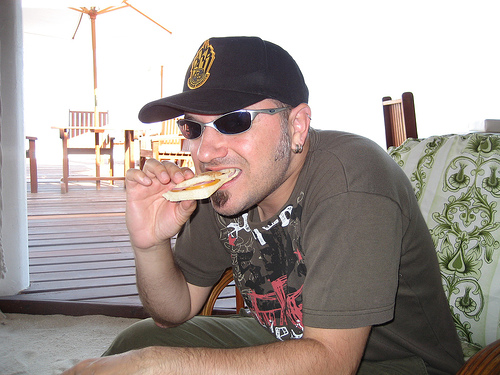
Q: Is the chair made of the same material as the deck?
A: Yes, both the chair and the deck are made of wood.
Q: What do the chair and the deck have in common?
A: The material, both the chair and the deck are wooden.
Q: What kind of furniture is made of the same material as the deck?
A: The chair is made of the same material as the deck.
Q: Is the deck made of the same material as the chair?
A: Yes, both the deck and the chair are made of wood.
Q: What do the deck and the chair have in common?
A: The material, both the deck and the chair are wooden.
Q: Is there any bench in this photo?
A: Yes, there is a bench.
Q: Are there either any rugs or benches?
A: Yes, there is a bench.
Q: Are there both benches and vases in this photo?
A: No, there is a bench but no vases.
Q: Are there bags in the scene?
A: No, there are no bags.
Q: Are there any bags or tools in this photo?
A: No, there are no bags or tools.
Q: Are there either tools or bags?
A: No, there are no bags or tools.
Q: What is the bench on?
A: The bench is on the deck.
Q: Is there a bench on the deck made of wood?
A: Yes, there is a bench on the deck.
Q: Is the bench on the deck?
A: Yes, the bench is on the deck.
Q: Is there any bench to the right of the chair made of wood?
A: Yes, there is a bench to the right of the chair.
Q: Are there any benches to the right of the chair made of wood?
A: Yes, there is a bench to the right of the chair.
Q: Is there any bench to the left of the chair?
A: No, the bench is to the right of the chair.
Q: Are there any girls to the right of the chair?
A: No, there is a bench to the right of the chair.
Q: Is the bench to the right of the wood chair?
A: Yes, the bench is to the right of the chair.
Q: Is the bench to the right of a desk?
A: No, the bench is to the right of the chair.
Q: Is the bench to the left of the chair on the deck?
A: No, the bench is to the right of the chair.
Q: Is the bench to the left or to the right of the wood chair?
A: The bench is to the right of the chair.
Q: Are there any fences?
A: No, there are no fences.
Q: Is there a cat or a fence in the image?
A: No, there are no fences or cats.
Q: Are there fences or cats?
A: No, there are no fences or cats.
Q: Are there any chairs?
A: Yes, there is a chair.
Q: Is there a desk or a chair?
A: Yes, there is a chair.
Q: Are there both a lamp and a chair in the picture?
A: No, there is a chair but no lamps.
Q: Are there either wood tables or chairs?
A: Yes, there is a wood chair.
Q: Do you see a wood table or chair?
A: Yes, there is a wood chair.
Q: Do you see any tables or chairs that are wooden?
A: Yes, the chair is wooden.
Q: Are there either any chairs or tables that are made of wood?
A: Yes, the chair is made of wood.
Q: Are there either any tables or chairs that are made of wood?
A: Yes, the chair is made of wood.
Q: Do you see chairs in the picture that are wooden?
A: Yes, there is a wood chair.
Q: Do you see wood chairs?
A: Yes, there is a wood chair.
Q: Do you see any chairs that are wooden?
A: Yes, there is a wood chair.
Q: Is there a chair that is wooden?
A: Yes, there is a chair that is wooden.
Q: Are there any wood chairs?
A: Yes, there is a chair that is made of wood.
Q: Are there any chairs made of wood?
A: Yes, there is a chair that is made of wood.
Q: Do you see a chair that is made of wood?
A: Yes, there is a chair that is made of wood.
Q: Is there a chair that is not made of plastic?
A: Yes, there is a chair that is made of wood.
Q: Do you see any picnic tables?
A: No, there are no picnic tables.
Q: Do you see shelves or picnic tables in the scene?
A: No, there are no picnic tables or shelves.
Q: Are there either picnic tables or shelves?
A: No, there are no picnic tables or shelves.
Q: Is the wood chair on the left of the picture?
A: Yes, the chair is on the left of the image.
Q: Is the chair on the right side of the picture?
A: No, the chair is on the left of the image.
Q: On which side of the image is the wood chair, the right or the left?
A: The chair is on the left of the image.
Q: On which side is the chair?
A: The chair is on the left of the image.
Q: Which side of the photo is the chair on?
A: The chair is on the left of the image.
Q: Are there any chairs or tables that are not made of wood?
A: No, there is a chair but it is made of wood.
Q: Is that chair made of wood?
A: Yes, the chair is made of wood.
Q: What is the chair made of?
A: The chair is made of wood.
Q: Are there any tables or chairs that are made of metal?
A: No, there is a chair but it is made of wood.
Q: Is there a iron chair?
A: No, there is a chair but it is made of wood.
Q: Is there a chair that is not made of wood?
A: No, there is a chair but it is made of wood.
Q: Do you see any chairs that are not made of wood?
A: No, there is a chair but it is made of wood.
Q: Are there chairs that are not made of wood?
A: No, there is a chair but it is made of wood.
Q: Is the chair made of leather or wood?
A: The chair is made of wood.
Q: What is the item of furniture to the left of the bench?
A: The piece of furniture is a chair.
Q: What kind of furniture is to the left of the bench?
A: The piece of furniture is a chair.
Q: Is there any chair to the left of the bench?
A: Yes, there is a chair to the left of the bench.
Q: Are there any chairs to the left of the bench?
A: Yes, there is a chair to the left of the bench.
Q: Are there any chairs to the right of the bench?
A: No, the chair is to the left of the bench.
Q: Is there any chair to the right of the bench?
A: No, the chair is to the left of the bench.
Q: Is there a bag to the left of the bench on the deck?
A: No, there is a chair to the left of the bench.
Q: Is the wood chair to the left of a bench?
A: Yes, the chair is to the left of a bench.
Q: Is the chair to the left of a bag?
A: No, the chair is to the left of a bench.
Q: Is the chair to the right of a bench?
A: No, the chair is to the left of a bench.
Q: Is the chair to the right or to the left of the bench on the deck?
A: The chair is to the left of the bench.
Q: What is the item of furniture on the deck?
A: The piece of furniture is a chair.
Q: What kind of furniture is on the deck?
A: The piece of furniture is a chair.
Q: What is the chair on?
A: The chair is on the deck.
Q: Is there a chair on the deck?
A: Yes, there is a chair on the deck.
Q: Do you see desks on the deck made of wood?
A: No, there is a chair on the deck.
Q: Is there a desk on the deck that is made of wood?
A: No, there is a chair on the deck.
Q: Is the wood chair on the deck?
A: Yes, the chair is on the deck.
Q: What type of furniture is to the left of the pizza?
A: The piece of furniture is a chair.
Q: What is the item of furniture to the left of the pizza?
A: The piece of furniture is a chair.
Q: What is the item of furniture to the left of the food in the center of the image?
A: The piece of furniture is a chair.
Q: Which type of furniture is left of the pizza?
A: The piece of furniture is a chair.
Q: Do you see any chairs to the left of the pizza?
A: Yes, there is a chair to the left of the pizza.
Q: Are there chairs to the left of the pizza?
A: Yes, there is a chair to the left of the pizza.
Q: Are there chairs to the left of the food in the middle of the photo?
A: Yes, there is a chair to the left of the pizza.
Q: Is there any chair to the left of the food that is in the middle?
A: Yes, there is a chair to the left of the pizza.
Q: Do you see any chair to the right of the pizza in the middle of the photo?
A: No, the chair is to the left of the pizza.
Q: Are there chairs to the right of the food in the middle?
A: No, the chair is to the left of the pizza.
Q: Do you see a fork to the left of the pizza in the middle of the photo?
A: No, there is a chair to the left of the pizza.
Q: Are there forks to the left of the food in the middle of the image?
A: No, there is a chair to the left of the pizza.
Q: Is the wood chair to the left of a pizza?
A: Yes, the chair is to the left of a pizza.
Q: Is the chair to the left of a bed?
A: No, the chair is to the left of a pizza.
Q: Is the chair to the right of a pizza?
A: No, the chair is to the left of a pizza.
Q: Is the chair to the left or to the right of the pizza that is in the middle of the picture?
A: The chair is to the left of the pizza.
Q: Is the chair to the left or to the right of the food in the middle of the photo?
A: The chair is to the left of the pizza.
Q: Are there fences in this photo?
A: No, there are no fences.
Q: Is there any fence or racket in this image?
A: No, there are no fences or rackets.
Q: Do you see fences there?
A: No, there are no fences.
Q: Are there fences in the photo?
A: No, there are no fences.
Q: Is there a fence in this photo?
A: No, there are no fences.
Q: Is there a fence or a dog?
A: No, there are no fences or dogs.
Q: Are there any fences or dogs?
A: No, there are no fences or dogs.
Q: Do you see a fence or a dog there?
A: No, there are no fences or dogs.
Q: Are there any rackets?
A: No, there are no rackets.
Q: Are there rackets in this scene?
A: No, there are no rackets.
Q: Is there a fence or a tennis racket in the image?
A: No, there are no rackets or fences.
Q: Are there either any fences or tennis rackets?
A: No, there are no tennis rackets or fences.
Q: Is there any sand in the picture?
A: Yes, there is sand.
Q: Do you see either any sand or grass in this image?
A: Yes, there is sand.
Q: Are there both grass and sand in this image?
A: No, there is sand but no grass.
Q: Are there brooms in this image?
A: No, there are no brooms.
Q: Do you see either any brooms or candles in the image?
A: No, there are no brooms or candles.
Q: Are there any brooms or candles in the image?
A: No, there are no brooms or candles.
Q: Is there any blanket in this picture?
A: Yes, there is a blanket.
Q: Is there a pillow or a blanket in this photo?
A: Yes, there is a blanket.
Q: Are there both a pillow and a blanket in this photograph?
A: No, there is a blanket but no pillows.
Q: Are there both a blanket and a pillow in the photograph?
A: No, there is a blanket but no pillows.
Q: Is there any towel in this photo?
A: No, there are no towels.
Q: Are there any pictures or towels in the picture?
A: No, there are no towels or pictures.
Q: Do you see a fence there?
A: No, there are no fences.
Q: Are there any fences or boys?
A: No, there are no fences or boys.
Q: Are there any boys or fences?
A: No, there are no fences or boys.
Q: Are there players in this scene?
A: No, there are no players.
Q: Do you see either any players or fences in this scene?
A: No, there are no players or fences.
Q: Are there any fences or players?
A: No, there are no players or fences.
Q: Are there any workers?
A: No, there are no workers.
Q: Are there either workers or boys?
A: No, there are no workers or boys.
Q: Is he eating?
A: Yes, the man is eating.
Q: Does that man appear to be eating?
A: Yes, the man is eating.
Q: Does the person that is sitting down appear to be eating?
A: Yes, the man is eating.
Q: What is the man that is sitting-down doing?
A: The man is eating.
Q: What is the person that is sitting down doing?
A: The man is eating.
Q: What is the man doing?
A: The man is eating.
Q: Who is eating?
A: The man is eating.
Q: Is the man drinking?
A: No, the man is eating.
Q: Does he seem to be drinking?
A: No, the man is eating.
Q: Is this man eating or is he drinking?
A: The man is eating.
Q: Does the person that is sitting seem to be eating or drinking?
A: The man is eating.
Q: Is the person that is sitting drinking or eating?
A: The man is eating.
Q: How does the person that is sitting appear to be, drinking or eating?
A: The man is eating.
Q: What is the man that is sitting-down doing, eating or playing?
A: The man is eating.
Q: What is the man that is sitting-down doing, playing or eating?
A: The man is eating.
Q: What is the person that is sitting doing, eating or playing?
A: The man is eating.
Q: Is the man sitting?
A: Yes, the man is sitting.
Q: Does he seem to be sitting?
A: Yes, the man is sitting.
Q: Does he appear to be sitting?
A: Yes, the man is sitting.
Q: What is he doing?
A: The man is sitting.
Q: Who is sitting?
A: The man is sitting.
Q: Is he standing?
A: No, the man is sitting.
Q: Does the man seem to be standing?
A: No, the man is sitting.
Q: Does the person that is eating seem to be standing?
A: No, the man is sitting.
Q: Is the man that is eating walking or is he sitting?
A: The man is sitting.